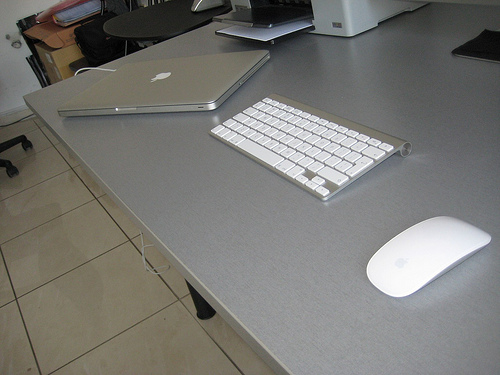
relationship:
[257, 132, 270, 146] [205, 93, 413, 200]
keyboard has key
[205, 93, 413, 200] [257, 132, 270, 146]
key on keyboard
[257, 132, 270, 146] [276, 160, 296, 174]
keyboard has key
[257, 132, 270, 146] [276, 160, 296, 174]
keyboard has a key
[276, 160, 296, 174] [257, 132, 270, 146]
key on keyboard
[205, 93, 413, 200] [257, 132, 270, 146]
key on a keyboard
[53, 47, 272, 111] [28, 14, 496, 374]
laptop on table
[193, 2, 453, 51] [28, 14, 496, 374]
printer on table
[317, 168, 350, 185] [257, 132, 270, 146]
key on a keyboard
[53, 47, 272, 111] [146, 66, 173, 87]
laptop has logo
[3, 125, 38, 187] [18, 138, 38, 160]
chair has wheel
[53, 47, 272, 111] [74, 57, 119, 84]
laptop has cord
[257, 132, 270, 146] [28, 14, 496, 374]
keyboard on table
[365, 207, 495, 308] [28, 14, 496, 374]
mouse on table